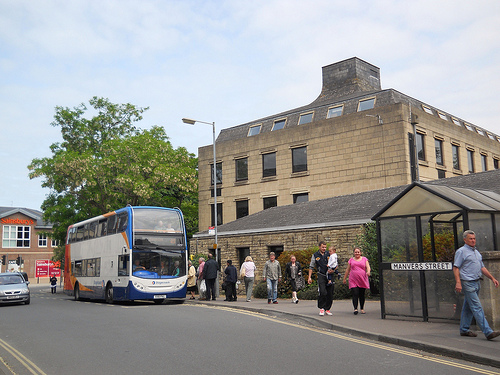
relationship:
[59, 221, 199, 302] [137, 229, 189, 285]
bus has glass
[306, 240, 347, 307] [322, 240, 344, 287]
man carrying baby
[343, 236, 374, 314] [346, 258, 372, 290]
woman wearing dress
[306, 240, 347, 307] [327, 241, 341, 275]
man carrying child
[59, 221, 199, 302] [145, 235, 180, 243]
bus has sign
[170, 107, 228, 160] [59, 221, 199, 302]
street lamp next to bus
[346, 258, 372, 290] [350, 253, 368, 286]
woman wearing shirt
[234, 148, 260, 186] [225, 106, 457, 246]
window on building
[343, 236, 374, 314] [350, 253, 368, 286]
woman wearing shirt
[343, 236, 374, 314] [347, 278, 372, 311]
woman wearing pants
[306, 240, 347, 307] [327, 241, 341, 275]
man holding child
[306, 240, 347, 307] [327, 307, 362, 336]
man on sidewalk